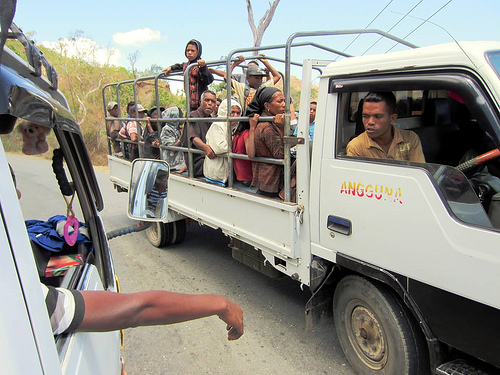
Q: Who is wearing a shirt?
A: The boy is wearing a shirt.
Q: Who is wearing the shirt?
A: The boy is wearing a shirt.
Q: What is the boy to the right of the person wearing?
A: The boy is wearing a shirt.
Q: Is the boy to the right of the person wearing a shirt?
A: Yes, the boy is wearing a shirt.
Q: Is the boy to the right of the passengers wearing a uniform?
A: No, the boy is wearing a shirt.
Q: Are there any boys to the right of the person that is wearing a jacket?
A: Yes, there is a boy to the right of the person.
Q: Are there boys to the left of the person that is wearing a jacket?
A: No, the boy is to the right of the person.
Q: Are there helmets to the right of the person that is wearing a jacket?
A: No, there is a boy to the right of the person.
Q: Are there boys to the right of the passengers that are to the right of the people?
A: Yes, there is a boy to the right of the passengers.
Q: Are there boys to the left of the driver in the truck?
A: Yes, there is a boy to the left of the driver.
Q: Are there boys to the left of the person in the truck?
A: Yes, there is a boy to the left of the driver.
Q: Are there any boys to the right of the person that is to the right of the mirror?
A: Yes, there is a boy to the right of the person.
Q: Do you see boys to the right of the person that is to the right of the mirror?
A: Yes, there is a boy to the right of the person.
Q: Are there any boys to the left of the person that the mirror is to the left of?
A: No, the boy is to the right of the person.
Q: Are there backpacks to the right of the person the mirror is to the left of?
A: No, there is a boy to the right of the person.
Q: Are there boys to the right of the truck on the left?
A: Yes, there is a boy to the right of the truck.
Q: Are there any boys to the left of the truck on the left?
A: No, the boy is to the right of the truck.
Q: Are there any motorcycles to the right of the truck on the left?
A: No, there is a boy to the right of the truck.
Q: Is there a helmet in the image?
A: No, there are no helmets.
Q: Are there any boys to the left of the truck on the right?
A: Yes, there is a boy to the left of the truck.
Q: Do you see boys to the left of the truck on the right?
A: Yes, there is a boy to the left of the truck.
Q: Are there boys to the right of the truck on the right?
A: No, the boy is to the left of the truck.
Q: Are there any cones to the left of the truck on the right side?
A: No, there is a boy to the left of the truck.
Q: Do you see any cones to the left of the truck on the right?
A: No, there is a boy to the left of the truck.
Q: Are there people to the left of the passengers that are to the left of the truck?
A: Yes, there are people to the left of the passengers.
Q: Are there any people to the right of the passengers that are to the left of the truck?
A: No, the people are to the left of the passengers.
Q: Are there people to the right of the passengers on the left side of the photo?
A: Yes, there are people to the right of the passengers.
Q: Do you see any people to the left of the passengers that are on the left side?
A: No, the people are to the right of the passengers.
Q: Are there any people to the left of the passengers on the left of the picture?
A: No, the people are to the right of the passengers.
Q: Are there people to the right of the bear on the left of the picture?
A: Yes, there are people to the right of the bear.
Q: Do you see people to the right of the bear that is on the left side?
A: Yes, there are people to the right of the bear.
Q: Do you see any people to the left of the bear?
A: No, the people are to the right of the bear.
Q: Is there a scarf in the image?
A: Yes, there is a scarf.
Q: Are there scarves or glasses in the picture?
A: Yes, there is a scarf.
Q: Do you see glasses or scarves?
A: Yes, there is a scarf.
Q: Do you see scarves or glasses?
A: Yes, there is a scarf.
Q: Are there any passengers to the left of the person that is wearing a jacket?
A: Yes, there are passengers to the left of the person.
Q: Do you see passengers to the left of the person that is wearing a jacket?
A: Yes, there are passengers to the left of the person.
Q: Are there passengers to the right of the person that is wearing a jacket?
A: No, the passengers are to the left of the person.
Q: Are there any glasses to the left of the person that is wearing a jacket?
A: No, there are passengers to the left of the person.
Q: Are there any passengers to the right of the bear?
A: Yes, there are passengers to the right of the bear.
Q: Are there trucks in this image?
A: Yes, there is a truck.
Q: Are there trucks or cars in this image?
A: Yes, there is a truck.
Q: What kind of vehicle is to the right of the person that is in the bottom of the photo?
A: The vehicle is a truck.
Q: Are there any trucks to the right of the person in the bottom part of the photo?
A: Yes, there is a truck to the right of the person.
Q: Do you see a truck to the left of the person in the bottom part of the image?
A: No, the truck is to the right of the person.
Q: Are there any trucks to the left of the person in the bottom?
A: No, the truck is to the right of the person.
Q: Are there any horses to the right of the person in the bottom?
A: No, there is a truck to the right of the person.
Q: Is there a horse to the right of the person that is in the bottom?
A: No, there is a truck to the right of the person.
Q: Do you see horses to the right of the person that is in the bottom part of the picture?
A: No, there is a truck to the right of the person.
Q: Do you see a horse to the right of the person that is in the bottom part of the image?
A: No, there is a truck to the right of the person.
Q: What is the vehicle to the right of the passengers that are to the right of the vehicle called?
A: The vehicle is a truck.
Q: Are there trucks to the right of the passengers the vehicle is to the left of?
A: Yes, there is a truck to the right of the passengers.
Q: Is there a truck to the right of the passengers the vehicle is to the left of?
A: Yes, there is a truck to the right of the passengers.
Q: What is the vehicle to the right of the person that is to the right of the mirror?
A: The vehicle is a truck.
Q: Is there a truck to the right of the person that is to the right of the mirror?
A: Yes, there is a truck to the right of the person.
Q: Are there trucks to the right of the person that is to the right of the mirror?
A: Yes, there is a truck to the right of the person.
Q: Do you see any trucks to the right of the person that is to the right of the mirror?
A: Yes, there is a truck to the right of the person.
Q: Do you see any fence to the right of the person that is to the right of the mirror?
A: No, there is a truck to the right of the person.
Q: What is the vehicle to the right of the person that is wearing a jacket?
A: The vehicle is a truck.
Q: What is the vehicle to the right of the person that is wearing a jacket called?
A: The vehicle is a truck.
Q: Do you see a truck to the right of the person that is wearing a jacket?
A: Yes, there is a truck to the right of the person.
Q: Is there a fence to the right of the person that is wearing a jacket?
A: No, there is a truck to the right of the person.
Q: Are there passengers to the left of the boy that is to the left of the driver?
A: Yes, there are passengers to the left of the boy.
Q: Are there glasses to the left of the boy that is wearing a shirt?
A: No, there are passengers to the left of the boy.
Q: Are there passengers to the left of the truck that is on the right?
A: Yes, there are passengers to the left of the truck.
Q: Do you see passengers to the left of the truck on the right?
A: Yes, there are passengers to the left of the truck.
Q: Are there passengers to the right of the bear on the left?
A: Yes, there are passengers to the right of the bear.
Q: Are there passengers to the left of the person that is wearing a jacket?
A: Yes, there are passengers to the left of the person.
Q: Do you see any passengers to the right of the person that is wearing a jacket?
A: No, the passengers are to the left of the person.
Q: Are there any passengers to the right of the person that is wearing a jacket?
A: No, the passengers are to the left of the person.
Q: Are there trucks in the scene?
A: Yes, there is a truck.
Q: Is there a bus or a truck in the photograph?
A: Yes, there is a truck.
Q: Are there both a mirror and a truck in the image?
A: Yes, there are both a truck and a mirror.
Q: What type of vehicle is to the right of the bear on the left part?
A: The vehicle is a truck.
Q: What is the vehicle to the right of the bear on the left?
A: The vehicle is a truck.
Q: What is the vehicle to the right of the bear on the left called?
A: The vehicle is a truck.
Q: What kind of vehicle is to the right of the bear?
A: The vehicle is a truck.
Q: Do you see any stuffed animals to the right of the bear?
A: No, there is a truck to the right of the bear.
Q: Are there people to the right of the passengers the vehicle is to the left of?
A: Yes, there is a person to the right of the passengers.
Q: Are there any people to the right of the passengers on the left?
A: Yes, there is a person to the right of the passengers.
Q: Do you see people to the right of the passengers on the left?
A: Yes, there is a person to the right of the passengers.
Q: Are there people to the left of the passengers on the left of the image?
A: No, the person is to the right of the passengers.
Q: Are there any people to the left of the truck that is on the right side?
A: Yes, there is a person to the left of the truck.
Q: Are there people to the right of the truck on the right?
A: No, the person is to the left of the truck.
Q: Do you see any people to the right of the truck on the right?
A: No, the person is to the left of the truck.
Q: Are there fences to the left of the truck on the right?
A: No, there is a person to the left of the truck.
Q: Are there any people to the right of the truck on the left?
A: Yes, there is a person to the right of the truck.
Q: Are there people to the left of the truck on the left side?
A: No, the person is to the right of the truck.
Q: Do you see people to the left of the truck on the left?
A: No, the person is to the right of the truck.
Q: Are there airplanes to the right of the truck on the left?
A: No, there is a person to the right of the truck.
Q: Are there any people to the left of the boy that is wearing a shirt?
A: Yes, there is a person to the left of the boy.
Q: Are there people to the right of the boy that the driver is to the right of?
A: No, the person is to the left of the boy.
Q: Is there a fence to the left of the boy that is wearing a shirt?
A: No, there is a person to the left of the boy.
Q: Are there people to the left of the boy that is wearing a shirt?
A: Yes, there is a person to the left of the boy.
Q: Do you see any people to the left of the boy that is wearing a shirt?
A: Yes, there is a person to the left of the boy.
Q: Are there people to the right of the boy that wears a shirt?
A: No, the person is to the left of the boy.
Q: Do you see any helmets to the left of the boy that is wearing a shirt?
A: No, there is a person to the left of the boy.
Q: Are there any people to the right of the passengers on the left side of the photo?
A: Yes, there is a person to the right of the passengers.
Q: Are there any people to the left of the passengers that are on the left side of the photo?
A: No, the person is to the right of the passengers.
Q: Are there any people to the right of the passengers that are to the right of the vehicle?
A: Yes, there is a person to the right of the passengers.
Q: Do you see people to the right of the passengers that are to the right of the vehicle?
A: Yes, there is a person to the right of the passengers.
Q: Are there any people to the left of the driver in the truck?
A: Yes, there is a person to the left of the driver.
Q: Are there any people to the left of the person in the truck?
A: Yes, there is a person to the left of the driver.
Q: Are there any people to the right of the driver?
A: No, the person is to the left of the driver.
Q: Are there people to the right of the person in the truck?
A: No, the person is to the left of the driver.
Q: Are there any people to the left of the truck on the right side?
A: Yes, there is a person to the left of the truck.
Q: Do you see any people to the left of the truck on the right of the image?
A: Yes, there is a person to the left of the truck.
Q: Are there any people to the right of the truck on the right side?
A: No, the person is to the left of the truck.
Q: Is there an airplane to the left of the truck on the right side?
A: No, there is a person to the left of the truck.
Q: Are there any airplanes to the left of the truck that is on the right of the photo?
A: No, there is a person to the left of the truck.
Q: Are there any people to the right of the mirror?
A: Yes, there is a person to the right of the mirror.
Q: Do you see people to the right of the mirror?
A: Yes, there is a person to the right of the mirror.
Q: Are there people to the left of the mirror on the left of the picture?
A: No, the person is to the right of the mirror.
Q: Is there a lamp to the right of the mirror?
A: No, there is a person to the right of the mirror.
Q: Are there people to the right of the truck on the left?
A: Yes, there is a person to the right of the truck.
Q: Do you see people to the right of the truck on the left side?
A: Yes, there is a person to the right of the truck.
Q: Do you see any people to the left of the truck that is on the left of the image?
A: No, the person is to the right of the truck.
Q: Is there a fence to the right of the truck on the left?
A: No, there is a person to the right of the truck.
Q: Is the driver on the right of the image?
A: Yes, the driver is on the right of the image.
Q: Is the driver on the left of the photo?
A: No, the driver is on the right of the image.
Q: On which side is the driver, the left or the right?
A: The driver is on the right of the image.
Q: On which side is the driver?
A: The driver is on the right of the image.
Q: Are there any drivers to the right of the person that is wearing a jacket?
A: Yes, there is a driver to the right of the person.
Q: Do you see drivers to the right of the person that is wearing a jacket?
A: Yes, there is a driver to the right of the person.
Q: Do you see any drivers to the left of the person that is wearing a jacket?
A: No, the driver is to the right of the person.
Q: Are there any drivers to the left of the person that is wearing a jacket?
A: No, the driver is to the right of the person.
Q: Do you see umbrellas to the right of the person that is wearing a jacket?
A: No, there is a driver to the right of the person.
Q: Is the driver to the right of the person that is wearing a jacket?
A: Yes, the driver is to the right of the person.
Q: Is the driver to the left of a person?
A: No, the driver is to the right of a person.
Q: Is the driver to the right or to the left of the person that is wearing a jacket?
A: The driver is to the right of the person.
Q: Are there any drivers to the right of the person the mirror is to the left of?
A: Yes, there is a driver to the right of the person.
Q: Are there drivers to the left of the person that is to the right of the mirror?
A: No, the driver is to the right of the person.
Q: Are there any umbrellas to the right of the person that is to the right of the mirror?
A: No, there is a driver to the right of the person.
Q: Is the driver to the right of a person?
A: Yes, the driver is to the right of a person.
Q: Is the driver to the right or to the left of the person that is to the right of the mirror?
A: The driver is to the right of the person.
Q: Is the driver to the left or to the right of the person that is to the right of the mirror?
A: The driver is to the right of the person.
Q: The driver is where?
A: The driver is in the truck.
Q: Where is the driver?
A: The driver is in the truck.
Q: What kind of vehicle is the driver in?
A: The driver is in the truck.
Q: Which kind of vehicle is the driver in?
A: The driver is in the truck.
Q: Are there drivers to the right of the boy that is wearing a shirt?
A: Yes, there is a driver to the right of the boy.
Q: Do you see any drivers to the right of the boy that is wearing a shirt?
A: Yes, there is a driver to the right of the boy.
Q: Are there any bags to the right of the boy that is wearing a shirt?
A: No, there is a driver to the right of the boy.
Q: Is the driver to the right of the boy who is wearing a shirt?
A: Yes, the driver is to the right of the boy.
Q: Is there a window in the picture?
A: Yes, there is a window.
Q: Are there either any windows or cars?
A: Yes, there is a window.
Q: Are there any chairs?
A: No, there are no chairs.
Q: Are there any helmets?
A: No, there are no helmets.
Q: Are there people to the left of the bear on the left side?
A: No, the person is to the right of the bear.